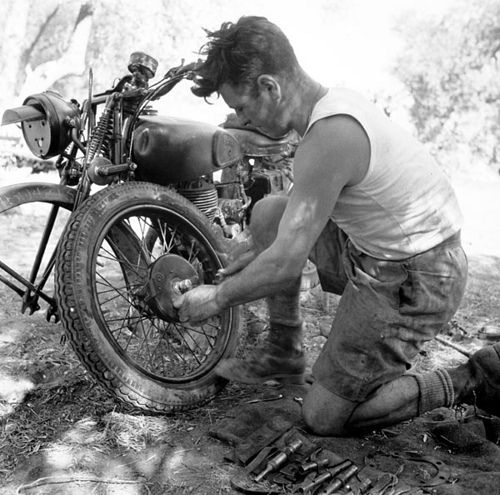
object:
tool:
[241, 432, 374, 494]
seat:
[225, 118, 297, 163]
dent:
[137, 128, 152, 157]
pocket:
[401, 267, 453, 316]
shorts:
[314, 219, 466, 399]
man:
[174, 34, 487, 447]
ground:
[0, 158, 500, 494]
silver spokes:
[95, 205, 232, 385]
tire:
[50, 175, 248, 414]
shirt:
[303, 83, 461, 261]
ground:
[312, 92, 367, 130]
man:
[177, 13, 499, 440]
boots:
[208, 341, 309, 384]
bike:
[0, 52, 298, 411]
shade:
[49, 390, 226, 495]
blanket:
[215, 340, 500, 494]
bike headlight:
[0, 90, 83, 165]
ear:
[255, 75, 282, 101]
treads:
[50, 202, 93, 327]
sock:
[409, 367, 456, 418]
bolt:
[179, 279, 194, 293]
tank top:
[308, 83, 464, 263]